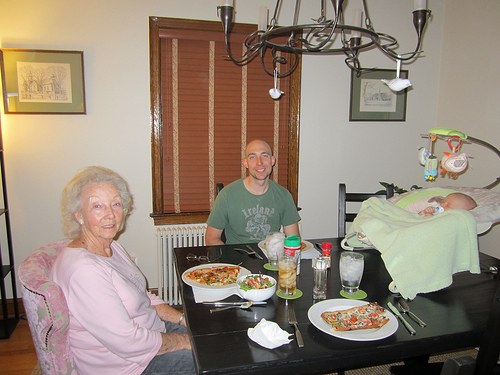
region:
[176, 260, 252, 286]
round white plate on table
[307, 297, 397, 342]
round white plate on table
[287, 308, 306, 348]
utensil on black table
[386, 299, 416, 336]
utensil on black table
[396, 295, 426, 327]
utensil on black table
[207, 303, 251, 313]
utensil on black table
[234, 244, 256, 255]
utensil on black table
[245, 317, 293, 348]
crumpled white paper napkin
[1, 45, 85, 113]
picture on the wall with a brown frame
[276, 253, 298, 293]
glass with ice and a brown beverage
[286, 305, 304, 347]
silver fork on the table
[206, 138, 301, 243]
bald man in green shirt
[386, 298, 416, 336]
silver butter knife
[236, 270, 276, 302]
white bowl of salad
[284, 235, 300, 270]
plastic bottle with green lid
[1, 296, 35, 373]
small section of hard wood floor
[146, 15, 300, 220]
window with brown blinds drawn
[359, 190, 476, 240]
sleeping baby with paci in bounce chair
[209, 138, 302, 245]
smiling seated man in green ireland shirt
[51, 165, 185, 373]
older woman in pink sweater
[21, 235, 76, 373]
curved back of chair with floral design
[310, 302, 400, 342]
white plate with pizza on it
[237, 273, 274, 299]
salad in a white bowl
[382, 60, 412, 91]
bird ornament hung from lighting fixture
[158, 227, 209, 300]
metal radiator for heat in the room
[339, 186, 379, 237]
back of black ladder back chair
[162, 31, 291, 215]
brown shutters over dining room window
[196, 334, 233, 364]
a table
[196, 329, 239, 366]
the table is black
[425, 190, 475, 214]
a baby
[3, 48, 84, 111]
a picture on the wall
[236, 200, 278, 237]
a design on the shirt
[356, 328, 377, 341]
the plate is white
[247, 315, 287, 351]
paper on the table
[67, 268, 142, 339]
the women is wearing pink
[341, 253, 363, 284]
ice in the glass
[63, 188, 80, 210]
the women has grey hair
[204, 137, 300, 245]
a man sitting at a table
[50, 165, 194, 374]
a woman sitting at a table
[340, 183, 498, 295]
a child in a portable bassinet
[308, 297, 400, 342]
a white plate with food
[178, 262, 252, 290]
a white plate with food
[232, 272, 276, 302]
a white bowl of salad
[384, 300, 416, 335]
a silver knife utensil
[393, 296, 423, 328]
a silver spoon utensil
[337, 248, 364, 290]
a clear glass of water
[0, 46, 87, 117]
a framed drawing on wall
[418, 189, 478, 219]
baby in a bouncer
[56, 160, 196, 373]
old woman at a table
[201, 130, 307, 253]
man at a table